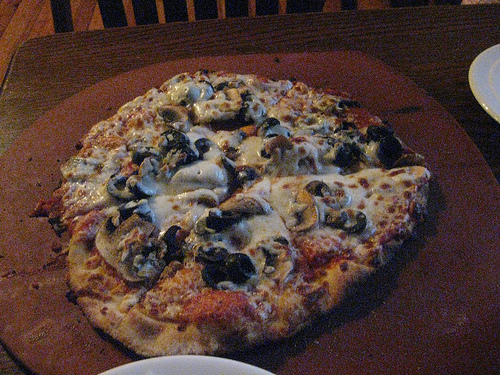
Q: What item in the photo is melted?
A: The browned mozzarella cheese.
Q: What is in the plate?
A: Pizz.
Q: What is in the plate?
A: Pizza.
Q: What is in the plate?
A: Cheese.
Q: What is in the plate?
A: Crust.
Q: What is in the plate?
A: Food.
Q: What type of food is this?
A: Pizza.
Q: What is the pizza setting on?
A: A table.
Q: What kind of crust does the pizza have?
A: Thin crust.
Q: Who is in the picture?
A: No one.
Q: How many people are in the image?
A: None.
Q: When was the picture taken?
A: At night.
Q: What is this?
A: A pizza.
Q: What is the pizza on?
A: A table.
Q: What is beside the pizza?
A: Plates.